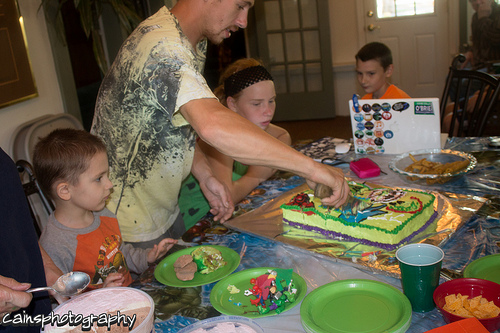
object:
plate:
[153, 242, 240, 287]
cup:
[394, 242, 446, 313]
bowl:
[434, 277, 499, 328]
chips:
[476, 300, 499, 316]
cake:
[283, 179, 439, 248]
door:
[248, 0, 339, 121]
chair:
[15, 113, 85, 176]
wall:
[0, 0, 88, 169]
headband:
[223, 64, 275, 95]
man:
[89, 0, 347, 248]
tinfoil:
[220, 171, 493, 276]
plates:
[300, 276, 414, 331]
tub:
[40, 285, 167, 332]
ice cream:
[45, 285, 152, 332]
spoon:
[24, 269, 92, 296]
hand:
[1, 275, 30, 325]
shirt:
[352, 87, 417, 151]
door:
[355, 0, 461, 115]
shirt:
[40, 206, 141, 289]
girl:
[209, 58, 292, 206]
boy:
[349, 41, 414, 147]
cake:
[192, 246, 224, 274]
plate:
[463, 251, 498, 285]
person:
[0, 137, 71, 331]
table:
[75, 135, 499, 333]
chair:
[437, 53, 499, 134]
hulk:
[157, 287, 214, 323]